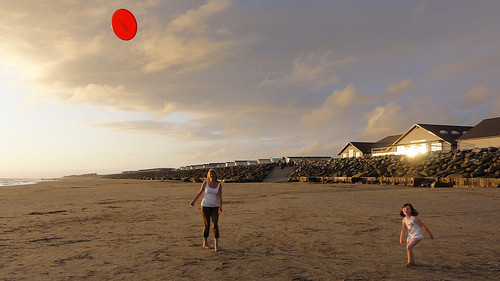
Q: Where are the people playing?
A: On the beach.